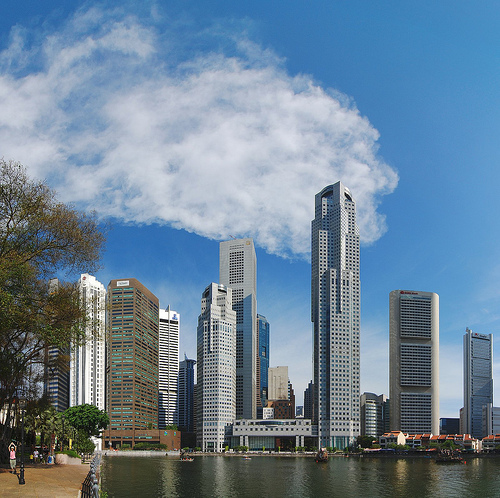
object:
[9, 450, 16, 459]
shirt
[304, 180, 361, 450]
building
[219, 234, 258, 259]
roof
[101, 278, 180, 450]
high rise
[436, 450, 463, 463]
boat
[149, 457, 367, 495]
water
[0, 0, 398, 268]
clouds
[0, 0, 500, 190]
sky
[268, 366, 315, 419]
distance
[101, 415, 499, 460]
harbor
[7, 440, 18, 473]
people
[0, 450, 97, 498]
walkway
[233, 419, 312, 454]
supports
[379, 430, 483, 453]
buildings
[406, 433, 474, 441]
roofs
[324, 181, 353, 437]
sides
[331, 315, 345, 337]
windows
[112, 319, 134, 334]
windows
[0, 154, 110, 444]
tree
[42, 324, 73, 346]
leaves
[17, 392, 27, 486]
pole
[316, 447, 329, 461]
boats